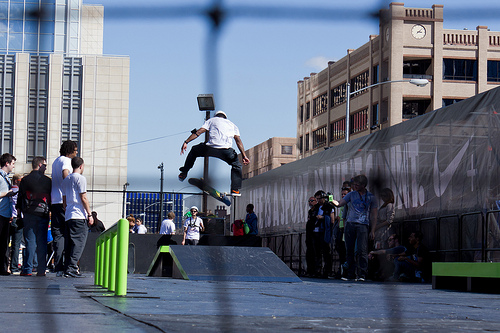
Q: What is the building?
A: Tan.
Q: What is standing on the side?
A: The people.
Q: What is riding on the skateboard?
A: The person.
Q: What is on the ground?
A: The low skateboard ramp.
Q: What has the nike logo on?
A: The large screen.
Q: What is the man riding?
A: Skateboard.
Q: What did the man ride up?
A: Ramp.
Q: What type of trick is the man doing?
A: Kickflip.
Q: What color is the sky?
A: Blue.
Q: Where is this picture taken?
A: A skate park.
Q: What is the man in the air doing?
A: Skateboarding.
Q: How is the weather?
A: Clear.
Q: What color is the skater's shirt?
A: White.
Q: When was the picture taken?
A: Daytime.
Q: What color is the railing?
A: Neon green.